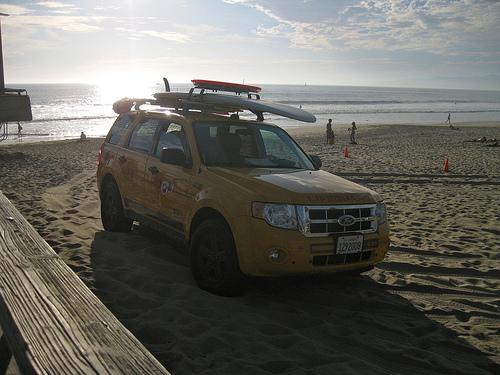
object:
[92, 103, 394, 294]
suv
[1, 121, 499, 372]
beach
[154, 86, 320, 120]
surfboard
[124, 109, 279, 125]
roof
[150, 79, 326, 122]
rack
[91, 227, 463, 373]
shadow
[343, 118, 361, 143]
people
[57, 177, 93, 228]
footprints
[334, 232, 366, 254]
tag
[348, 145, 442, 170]
cones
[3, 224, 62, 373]
railing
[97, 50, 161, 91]
sun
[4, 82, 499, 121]
ocean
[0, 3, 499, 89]
sky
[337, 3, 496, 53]
clouds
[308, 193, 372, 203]
words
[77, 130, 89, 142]
person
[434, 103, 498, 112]
waves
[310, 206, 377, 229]
grill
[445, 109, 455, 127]
person